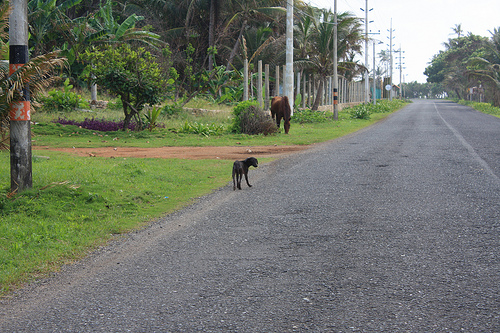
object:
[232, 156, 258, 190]
animal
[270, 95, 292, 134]
animal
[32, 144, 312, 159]
dirt driveway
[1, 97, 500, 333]
main road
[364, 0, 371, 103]
telephone pole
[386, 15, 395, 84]
telephone pole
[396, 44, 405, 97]
telephone pole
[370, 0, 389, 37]
wire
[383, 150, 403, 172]
ground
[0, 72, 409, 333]
road side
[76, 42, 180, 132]
trees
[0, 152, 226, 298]
green grass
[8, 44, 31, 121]
sign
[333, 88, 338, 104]
sign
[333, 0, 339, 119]
pole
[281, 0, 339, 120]
poles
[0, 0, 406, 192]
power poles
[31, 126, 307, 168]
dirt road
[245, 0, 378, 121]
poles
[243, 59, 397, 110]
fence